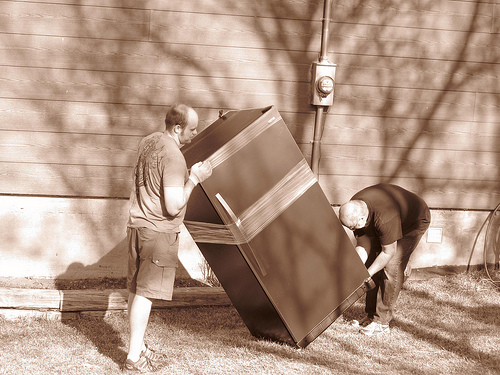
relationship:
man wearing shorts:
[126, 103, 213, 372] [126, 226, 176, 301]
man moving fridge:
[126, 103, 213, 372] [178, 107, 377, 350]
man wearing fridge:
[339, 183, 429, 333] [178, 107, 377, 350]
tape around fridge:
[182, 159, 319, 248] [178, 107, 377, 350]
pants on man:
[372, 224, 429, 322] [340, 166, 440, 316]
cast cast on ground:
[56, 231, 500, 375] [6, 273, 496, 373]